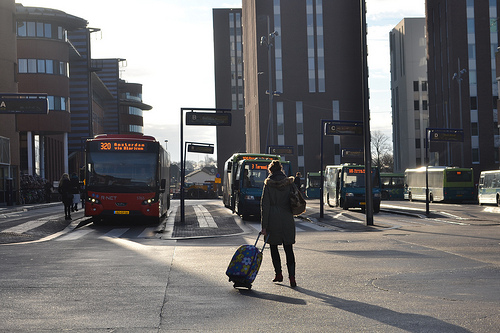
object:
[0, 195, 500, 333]
ground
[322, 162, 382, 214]
blue bus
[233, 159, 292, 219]
blue bus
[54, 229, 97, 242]
lines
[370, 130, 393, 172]
tree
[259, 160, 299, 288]
woman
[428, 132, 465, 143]
sign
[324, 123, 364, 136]
sign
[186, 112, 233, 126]
sign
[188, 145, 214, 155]
sign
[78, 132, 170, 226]
bus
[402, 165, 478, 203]
bus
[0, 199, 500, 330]
road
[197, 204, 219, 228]
lines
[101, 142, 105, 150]
number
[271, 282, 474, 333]
shadow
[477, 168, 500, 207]
bus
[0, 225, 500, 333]
paved road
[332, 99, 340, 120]
window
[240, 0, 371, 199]
building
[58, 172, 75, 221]
passenger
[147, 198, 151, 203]
lights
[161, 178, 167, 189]
side mirror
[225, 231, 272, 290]
floral suitcase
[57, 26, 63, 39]
windows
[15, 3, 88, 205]
building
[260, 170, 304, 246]
coat